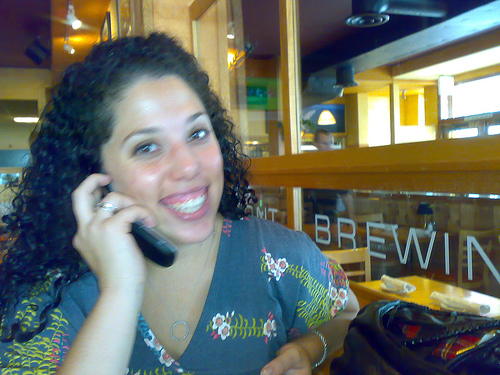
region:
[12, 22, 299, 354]
smiling lady on a cell phone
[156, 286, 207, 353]
silver circle charm on a necklace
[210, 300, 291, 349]
yellow centered daisy on a shirt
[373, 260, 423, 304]
rolled up napkin with utensils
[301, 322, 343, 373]
diamond tennis bracelet on arm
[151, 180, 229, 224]
smile showing too much gum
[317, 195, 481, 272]
long black curly hair glass divider at a restaurant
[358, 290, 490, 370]
big black purse on table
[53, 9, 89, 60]
directional lighting on the ceiling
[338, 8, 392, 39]
circular ceiling vent at a restaurant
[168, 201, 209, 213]
The teeth of the girl.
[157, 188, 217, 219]
The lips of the girl.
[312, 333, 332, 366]
The bracelet on the girl's wrist.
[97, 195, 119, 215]
The rings on the girl's finger.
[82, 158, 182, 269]
The black cell phone the girl has in her hand.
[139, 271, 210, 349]
The necklace the girl is wearing.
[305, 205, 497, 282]
The word BREWIN on the glass to the right of the girl.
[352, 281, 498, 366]
The black purse to the right of the girl.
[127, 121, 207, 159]
The eyes of the girl.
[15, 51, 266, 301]
The curly hair of the girl.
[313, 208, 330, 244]
a white capital letter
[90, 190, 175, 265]
a long black phone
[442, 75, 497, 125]
a small window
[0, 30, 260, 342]
a woman's black curly hair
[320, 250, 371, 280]
a wooden chair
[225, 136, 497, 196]
a brown wooden beam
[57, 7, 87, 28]
a white hanging light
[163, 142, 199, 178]
the nose of a woman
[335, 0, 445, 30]
a ceiling exhaust fan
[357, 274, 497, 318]
a brown wooden table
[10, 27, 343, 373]
A woman talking on a phone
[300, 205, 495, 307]
White letters on glass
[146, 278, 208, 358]
woman wears a round diamond necklace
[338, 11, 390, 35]
a round speaker in ceiling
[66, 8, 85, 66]
white lights in the ceiling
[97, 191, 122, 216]
Woman wears a ring on her finger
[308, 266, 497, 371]
A black bag sits by the woman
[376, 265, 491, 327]
Two utensil rolls inside napkins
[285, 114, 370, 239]
A man walking on the other side of the glass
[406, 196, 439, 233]
a little black lamp on the table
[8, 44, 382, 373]
A young woman smiling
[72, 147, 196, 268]
a cell phone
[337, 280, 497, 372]
a black bag on a table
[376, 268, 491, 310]
silverware rolled in napkins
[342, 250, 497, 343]
a wooden table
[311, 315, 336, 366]
bracelet on the woman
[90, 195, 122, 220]
ring on the woman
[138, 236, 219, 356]
necklace on the woman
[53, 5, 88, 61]
lights hanging from the ceiling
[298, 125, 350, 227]
a man walking